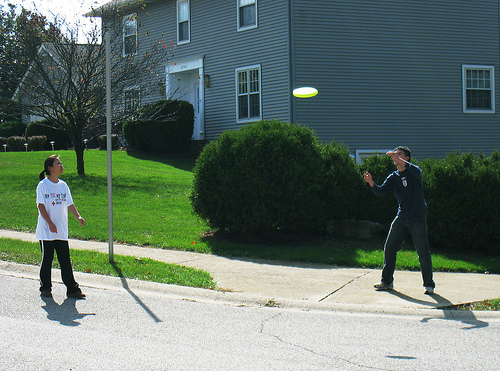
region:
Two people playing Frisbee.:
[31, 83, 436, 298]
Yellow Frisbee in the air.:
[291, 87, 318, 97]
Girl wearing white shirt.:
[30, 180, 75, 242]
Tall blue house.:
[82, 2, 495, 178]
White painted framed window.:
[235, 65, 262, 120]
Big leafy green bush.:
[190, 121, 365, 241]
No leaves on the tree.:
[16, 0, 198, 177]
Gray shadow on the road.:
[30, 293, 95, 323]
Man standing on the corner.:
[210, 141, 440, 317]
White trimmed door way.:
[162, 52, 207, 147]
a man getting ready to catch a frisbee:
[283, 73, 451, 303]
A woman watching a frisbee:
[21, 79, 336, 309]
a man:
[358, 137, 464, 309]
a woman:
[22, 141, 104, 315]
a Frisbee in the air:
[272, 72, 334, 114]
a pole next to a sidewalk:
[89, 22, 156, 275]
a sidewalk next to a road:
[153, 235, 355, 368]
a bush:
[186, 117, 366, 253]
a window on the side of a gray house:
[329, 0, 496, 142]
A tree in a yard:
[8, 2, 159, 174]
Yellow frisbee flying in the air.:
[291, 81, 323, 101]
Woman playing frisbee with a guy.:
[35, 150, 91, 306]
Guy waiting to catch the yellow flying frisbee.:
[358, 141, 443, 303]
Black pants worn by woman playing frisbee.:
[39, 238, 74, 292]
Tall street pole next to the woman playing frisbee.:
[99, 30, 127, 267]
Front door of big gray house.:
[166, 63, 211, 138]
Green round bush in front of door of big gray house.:
[122, 98, 197, 158]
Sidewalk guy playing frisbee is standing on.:
[318, 267, 499, 306]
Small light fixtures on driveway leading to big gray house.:
[2, 142, 97, 153]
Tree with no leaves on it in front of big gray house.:
[7, 6, 175, 184]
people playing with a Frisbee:
[22, 73, 450, 312]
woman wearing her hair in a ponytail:
[25, 145, 66, 183]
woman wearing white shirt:
[26, 175, 71, 235]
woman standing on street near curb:
[10, 255, 170, 320]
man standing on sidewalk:
[350, 115, 460, 300]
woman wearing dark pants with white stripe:
[30, 235, 95, 295]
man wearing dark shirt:
[365, 160, 435, 210]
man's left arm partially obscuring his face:
[375, 135, 420, 175]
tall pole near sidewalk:
[95, 25, 125, 270]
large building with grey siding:
[90, 0, 495, 166]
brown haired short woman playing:
[34, 150, 86, 300]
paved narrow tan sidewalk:
[0, 220, 497, 305]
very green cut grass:
[0, 145, 499, 320]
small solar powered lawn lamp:
[2, 142, 11, 152]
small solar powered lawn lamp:
[22, 139, 32, 150]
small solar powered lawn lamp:
[48, 139, 55, 148]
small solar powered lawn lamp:
[82, 134, 92, 147]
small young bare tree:
[3, 3, 168, 177]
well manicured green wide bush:
[194, 122, 361, 242]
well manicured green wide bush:
[121, 95, 193, 149]